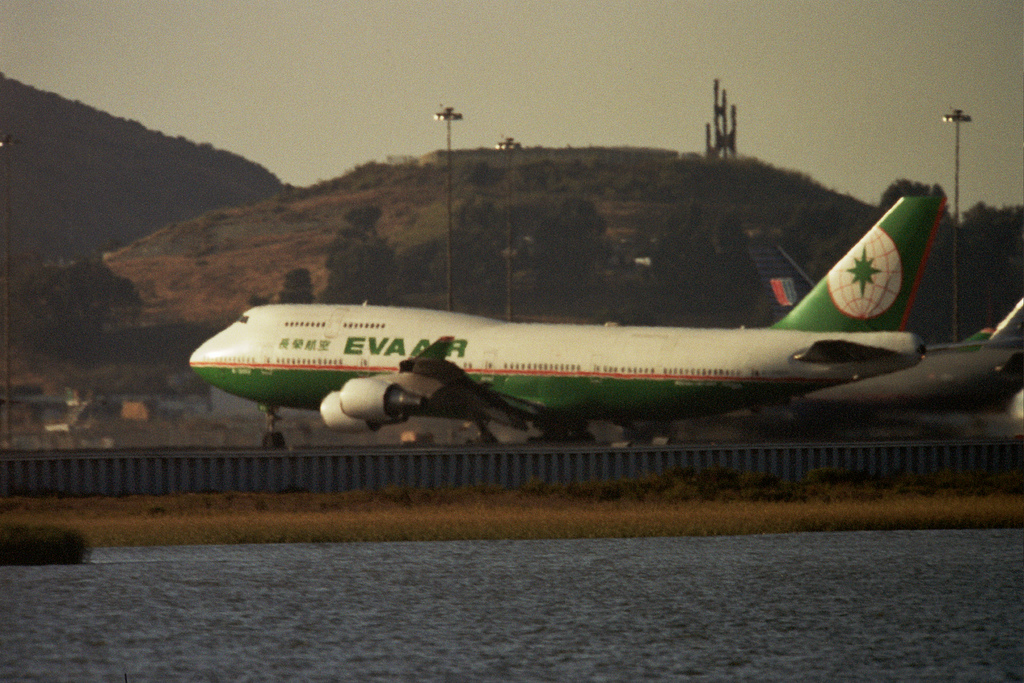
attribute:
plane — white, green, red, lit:
[144, 172, 960, 427]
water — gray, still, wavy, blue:
[20, 521, 1008, 679]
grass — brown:
[10, 494, 1005, 534]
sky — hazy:
[5, 3, 1005, 199]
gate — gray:
[16, 434, 1012, 495]